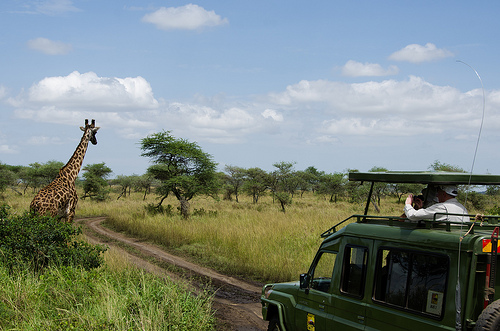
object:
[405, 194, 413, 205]
hand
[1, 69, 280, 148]
clouds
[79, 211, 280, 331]
pathway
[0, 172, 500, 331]
wilderness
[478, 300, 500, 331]
tire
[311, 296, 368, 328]
doors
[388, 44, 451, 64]
cloud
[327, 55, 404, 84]
cloud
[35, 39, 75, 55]
cloud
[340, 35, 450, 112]
white clouds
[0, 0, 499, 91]
blue sky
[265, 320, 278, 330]
tire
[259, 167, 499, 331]
vehicle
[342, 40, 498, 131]
clouds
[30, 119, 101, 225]
adult giraffe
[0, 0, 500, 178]
sky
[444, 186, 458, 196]
hat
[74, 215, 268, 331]
road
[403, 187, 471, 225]
man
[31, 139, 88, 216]
spots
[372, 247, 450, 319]
windows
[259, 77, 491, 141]
clouds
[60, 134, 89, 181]
neck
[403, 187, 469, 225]
guy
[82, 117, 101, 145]
head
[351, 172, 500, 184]
canopy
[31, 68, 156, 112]
cloud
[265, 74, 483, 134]
cloud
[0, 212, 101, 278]
bushes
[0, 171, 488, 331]
plain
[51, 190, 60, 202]
spot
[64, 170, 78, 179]
spot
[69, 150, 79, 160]
spot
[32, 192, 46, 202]
spot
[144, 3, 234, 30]
cloud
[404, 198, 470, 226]
shirt